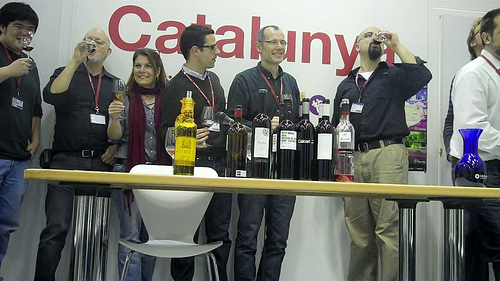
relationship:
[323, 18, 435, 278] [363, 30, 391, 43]
man drinking glass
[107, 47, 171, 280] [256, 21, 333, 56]
woman holding glass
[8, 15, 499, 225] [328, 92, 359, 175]
people tasting wine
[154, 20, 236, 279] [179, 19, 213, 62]
man with hair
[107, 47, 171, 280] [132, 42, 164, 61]
woman with brown hair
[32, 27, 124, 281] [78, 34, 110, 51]
man with glasses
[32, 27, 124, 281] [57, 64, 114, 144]
man with black shirt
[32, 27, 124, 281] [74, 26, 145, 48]
man with glasses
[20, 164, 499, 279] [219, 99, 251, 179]
table with wine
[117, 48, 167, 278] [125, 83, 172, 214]
woman has scarf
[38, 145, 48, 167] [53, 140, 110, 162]
phone case on belt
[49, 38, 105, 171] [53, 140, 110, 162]
man has belt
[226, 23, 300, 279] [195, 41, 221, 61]
man has glasses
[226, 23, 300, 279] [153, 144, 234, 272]
man has jeans